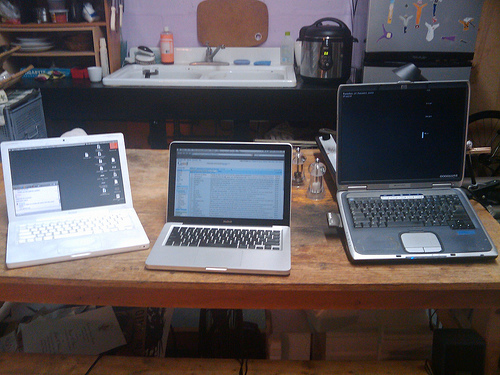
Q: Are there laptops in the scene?
A: Yes, there is a laptop.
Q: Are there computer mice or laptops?
A: Yes, there is a laptop.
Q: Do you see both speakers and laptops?
A: No, there is a laptop but no speakers.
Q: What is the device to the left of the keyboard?
A: The device is a laptop.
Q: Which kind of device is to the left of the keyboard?
A: The device is a laptop.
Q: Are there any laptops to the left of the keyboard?
A: Yes, there is a laptop to the left of the keyboard.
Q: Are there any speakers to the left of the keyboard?
A: No, there is a laptop to the left of the keyboard.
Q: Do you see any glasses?
A: No, there are no glasses.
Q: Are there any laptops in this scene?
A: Yes, there is a laptop.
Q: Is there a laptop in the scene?
A: Yes, there is a laptop.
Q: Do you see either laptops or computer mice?
A: Yes, there is a laptop.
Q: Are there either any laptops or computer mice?
A: Yes, there is a laptop.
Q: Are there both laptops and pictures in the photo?
A: No, there is a laptop but no pictures.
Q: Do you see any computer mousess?
A: No, there are no computer mousess.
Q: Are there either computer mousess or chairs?
A: No, there are no computer mousess or chairs.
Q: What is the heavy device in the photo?
A: The device is a laptop.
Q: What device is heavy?
A: The device is a laptop.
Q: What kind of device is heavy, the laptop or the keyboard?
A: The laptop is heavy.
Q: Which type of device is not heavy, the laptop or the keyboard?
A: The keyboard is not heavy.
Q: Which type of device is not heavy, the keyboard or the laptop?
A: The keyboard is not heavy.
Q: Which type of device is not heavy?
A: The device is a keyboard.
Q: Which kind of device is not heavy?
A: The device is a keyboard.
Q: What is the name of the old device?
A: The device is a laptop.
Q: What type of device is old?
A: The device is a laptop.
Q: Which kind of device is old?
A: The device is a laptop.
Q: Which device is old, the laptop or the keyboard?
A: The laptop is old.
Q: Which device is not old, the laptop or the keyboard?
A: The keyboard is not old.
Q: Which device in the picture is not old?
A: The device is a keyboard.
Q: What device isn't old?
A: The device is a keyboard.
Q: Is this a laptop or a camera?
A: This is a laptop.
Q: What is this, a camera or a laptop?
A: This is a laptop.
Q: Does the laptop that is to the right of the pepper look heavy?
A: Yes, the laptop computer is heavy.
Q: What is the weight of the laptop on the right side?
A: The laptop computer is heavy.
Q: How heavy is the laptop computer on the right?
A: The laptop is heavy.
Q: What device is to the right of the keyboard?
A: The device is a laptop.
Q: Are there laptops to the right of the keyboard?
A: Yes, there is a laptop to the right of the keyboard.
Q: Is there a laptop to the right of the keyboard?
A: Yes, there is a laptop to the right of the keyboard.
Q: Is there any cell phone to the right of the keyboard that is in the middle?
A: No, there is a laptop to the right of the keyboard.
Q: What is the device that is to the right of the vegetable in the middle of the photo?
A: The device is a laptop.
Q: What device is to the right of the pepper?
A: The device is a laptop.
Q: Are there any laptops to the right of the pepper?
A: Yes, there is a laptop to the right of the pepper.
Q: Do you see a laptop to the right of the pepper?
A: Yes, there is a laptop to the right of the pepper.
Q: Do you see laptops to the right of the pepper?
A: Yes, there is a laptop to the right of the pepper.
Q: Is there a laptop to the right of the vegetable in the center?
A: Yes, there is a laptop to the right of the pepper.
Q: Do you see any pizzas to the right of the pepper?
A: No, there is a laptop to the right of the pepper.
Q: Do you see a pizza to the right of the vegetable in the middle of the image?
A: No, there is a laptop to the right of the pepper.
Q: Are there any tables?
A: Yes, there is a table.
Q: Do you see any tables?
A: Yes, there is a table.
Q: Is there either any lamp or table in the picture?
A: Yes, there is a table.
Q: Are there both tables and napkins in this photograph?
A: No, there is a table but no napkins.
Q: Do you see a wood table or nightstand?
A: Yes, there is a wood table.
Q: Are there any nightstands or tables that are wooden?
A: Yes, the table is wooden.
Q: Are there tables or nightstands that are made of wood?
A: Yes, the table is made of wood.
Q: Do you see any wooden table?
A: Yes, there is a wood table.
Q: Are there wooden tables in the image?
A: Yes, there is a wood table.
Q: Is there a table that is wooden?
A: Yes, there is a table that is wooden.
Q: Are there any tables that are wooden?
A: Yes, there is a table that is wooden.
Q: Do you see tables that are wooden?
A: Yes, there is a table that is wooden.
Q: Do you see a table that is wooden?
A: Yes, there is a table that is wooden.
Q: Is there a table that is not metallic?
A: Yes, there is a wooden table.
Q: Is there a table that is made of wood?
A: Yes, there is a table that is made of wood.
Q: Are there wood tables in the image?
A: Yes, there is a table that is made of wood.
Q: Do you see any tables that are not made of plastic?
A: Yes, there is a table that is made of wood.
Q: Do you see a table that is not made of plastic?
A: Yes, there is a table that is made of wood.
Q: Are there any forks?
A: No, there are no forks.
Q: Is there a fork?
A: No, there are no forks.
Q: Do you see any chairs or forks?
A: No, there are no forks or chairs.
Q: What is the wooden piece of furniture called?
A: The piece of furniture is a table.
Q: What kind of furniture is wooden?
A: The furniture is a table.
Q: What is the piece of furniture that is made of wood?
A: The piece of furniture is a table.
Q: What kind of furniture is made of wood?
A: The furniture is a table.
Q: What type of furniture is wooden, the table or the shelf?
A: The table is wooden.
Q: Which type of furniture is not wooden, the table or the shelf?
A: The shelf is not wooden.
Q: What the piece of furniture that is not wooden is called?
A: The piece of furniture is a shelf.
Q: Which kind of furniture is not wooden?
A: The furniture is a shelf.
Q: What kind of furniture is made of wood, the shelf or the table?
A: The table is made of wood.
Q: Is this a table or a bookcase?
A: This is a table.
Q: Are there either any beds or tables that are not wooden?
A: No, there is a table but it is wooden.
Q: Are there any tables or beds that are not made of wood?
A: No, there is a table but it is made of wood.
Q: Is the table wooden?
A: Yes, the table is wooden.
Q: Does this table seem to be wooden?
A: Yes, the table is wooden.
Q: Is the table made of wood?
A: Yes, the table is made of wood.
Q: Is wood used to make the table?
A: Yes, the table is made of wood.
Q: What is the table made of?
A: The table is made of wood.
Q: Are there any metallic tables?
A: No, there is a table but it is wooden.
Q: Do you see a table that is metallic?
A: No, there is a table but it is wooden.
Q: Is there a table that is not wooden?
A: No, there is a table but it is wooden.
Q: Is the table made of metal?
A: No, the table is made of wood.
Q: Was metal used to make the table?
A: No, the table is made of wood.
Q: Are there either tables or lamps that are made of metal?
A: No, there is a table but it is made of wood.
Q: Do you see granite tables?
A: No, there is a table but it is made of wood.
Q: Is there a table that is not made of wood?
A: No, there is a table but it is made of wood.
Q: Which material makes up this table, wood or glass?
A: The table is made of wood.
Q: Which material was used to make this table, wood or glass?
A: The table is made of wood.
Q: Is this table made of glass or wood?
A: The table is made of wood.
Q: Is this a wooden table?
A: Yes, this is a wooden table.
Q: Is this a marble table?
A: No, this is a wooden table.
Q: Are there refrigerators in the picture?
A: Yes, there is a refrigerator.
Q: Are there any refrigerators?
A: Yes, there is a refrigerator.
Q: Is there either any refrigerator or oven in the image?
A: Yes, there is a refrigerator.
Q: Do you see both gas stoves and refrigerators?
A: No, there is a refrigerator but no gas stoves.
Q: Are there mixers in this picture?
A: No, there are no mixers.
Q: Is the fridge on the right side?
A: Yes, the fridge is on the right of the image.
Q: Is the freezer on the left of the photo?
A: No, the freezer is on the right of the image.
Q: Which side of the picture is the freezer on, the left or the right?
A: The freezer is on the right of the image.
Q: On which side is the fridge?
A: The fridge is on the right of the image.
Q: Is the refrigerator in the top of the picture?
A: Yes, the refrigerator is in the top of the image.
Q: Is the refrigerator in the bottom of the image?
A: No, the refrigerator is in the top of the image.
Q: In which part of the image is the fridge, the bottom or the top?
A: The fridge is in the top of the image.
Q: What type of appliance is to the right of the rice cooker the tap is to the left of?
A: The appliance is a refrigerator.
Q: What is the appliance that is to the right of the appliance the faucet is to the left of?
A: The appliance is a refrigerator.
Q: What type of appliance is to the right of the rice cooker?
A: The appliance is a refrigerator.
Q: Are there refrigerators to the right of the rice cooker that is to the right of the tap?
A: Yes, there is a refrigerator to the right of the rice cooker.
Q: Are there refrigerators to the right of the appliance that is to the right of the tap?
A: Yes, there is a refrigerator to the right of the rice cooker.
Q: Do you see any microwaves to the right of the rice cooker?
A: No, there is a refrigerator to the right of the rice cooker.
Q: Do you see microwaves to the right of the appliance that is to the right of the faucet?
A: No, there is a refrigerator to the right of the rice cooker.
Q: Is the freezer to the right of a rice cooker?
A: Yes, the freezer is to the right of a rice cooker.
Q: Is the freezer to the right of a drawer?
A: No, the freezer is to the right of a rice cooker.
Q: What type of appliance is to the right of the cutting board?
A: The appliance is a refrigerator.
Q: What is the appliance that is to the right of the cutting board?
A: The appliance is a refrigerator.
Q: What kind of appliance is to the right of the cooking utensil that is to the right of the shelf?
A: The appliance is a refrigerator.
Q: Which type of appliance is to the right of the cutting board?
A: The appliance is a refrigerator.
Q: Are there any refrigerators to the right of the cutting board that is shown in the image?
A: Yes, there is a refrigerator to the right of the cutting board.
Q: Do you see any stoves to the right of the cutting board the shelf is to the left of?
A: No, there is a refrigerator to the right of the cutting board.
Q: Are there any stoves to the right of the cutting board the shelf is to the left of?
A: No, there is a refrigerator to the right of the cutting board.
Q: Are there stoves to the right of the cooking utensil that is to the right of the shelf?
A: No, there is a refrigerator to the right of the cutting board.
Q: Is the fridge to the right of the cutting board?
A: Yes, the fridge is to the right of the cutting board.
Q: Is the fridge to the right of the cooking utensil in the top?
A: Yes, the fridge is to the right of the cutting board.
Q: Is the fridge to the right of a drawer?
A: No, the fridge is to the right of the cutting board.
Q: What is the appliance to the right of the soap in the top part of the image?
A: The appliance is a refrigerator.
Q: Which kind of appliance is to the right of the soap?
A: The appliance is a refrigerator.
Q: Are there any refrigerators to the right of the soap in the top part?
A: Yes, there is a refrigerator to the right of the soap.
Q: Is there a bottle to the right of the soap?
A: No, there is a refrigerator to the right of the soap.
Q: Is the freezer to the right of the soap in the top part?
A: Yes, the freezer is to the right of the soap.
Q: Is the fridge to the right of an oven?
A: No, the fridge is to the right of the soap.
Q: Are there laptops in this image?
A: Yes, there is a laptop.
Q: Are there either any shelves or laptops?
A: Yes, there is a laptop.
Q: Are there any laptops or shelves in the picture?
A: Yes, there is a laptop.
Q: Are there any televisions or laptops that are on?
A: Yes, the laptop is on.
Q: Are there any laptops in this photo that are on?
A: Yes, there is a laptop that is on.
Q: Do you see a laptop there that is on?
A: Yes, there is a laptop that is on.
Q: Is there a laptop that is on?
A: Yes, there is a laptop that is on.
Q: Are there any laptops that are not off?
A: Yes, there is a laptop that is on.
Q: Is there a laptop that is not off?
A: Yes, there is a laptop that is on.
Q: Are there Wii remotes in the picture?
A: No, there are no Wii remotes.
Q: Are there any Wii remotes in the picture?
A: No, there are no Wii remotes.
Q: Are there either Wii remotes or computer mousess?
A: No, there are no Wii remotes or computer mousess.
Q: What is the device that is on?
A: The device is a laptop.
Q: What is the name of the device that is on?
A: The device is a laptop.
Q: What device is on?
A: The device is a laptop.